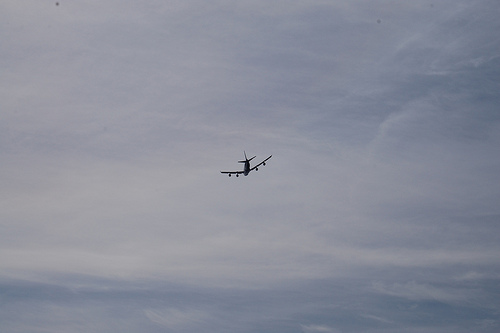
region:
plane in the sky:
[212, 144, 283, 192]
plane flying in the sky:
[212, 141, 277, 190]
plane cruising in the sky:
[213, 140, 280, 196]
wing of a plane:
[214, 162, 250, 180]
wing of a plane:
[248, 149, 275, 179]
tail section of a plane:
[233, 147, 259, 168]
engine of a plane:
[227, 166, 233, 179]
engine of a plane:
[231, 169, 241, 179]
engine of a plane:
[252, 163, 260, 172]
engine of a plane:
[260, 159, 271, 168]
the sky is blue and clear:
[82, 97, 251, 329]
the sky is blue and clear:
[18, 8, 159, 159]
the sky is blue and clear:
[99, 190, 211, 332]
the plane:
[206, 111, 333, 246]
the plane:
[176, 119, 312, 319]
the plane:
[181, 41, 363, 327]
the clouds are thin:
[77, 142, 166, 276]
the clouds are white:
[345, 64, 423, 231]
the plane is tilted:
[222, 141, 281, 193]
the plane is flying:
[206, 139, 276, 191]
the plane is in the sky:
[215, 135, 284, 202]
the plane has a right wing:
[252, 145, 278, 170]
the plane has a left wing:
[217, 163, 243, 181]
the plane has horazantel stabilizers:
[230, 155, 258, 164]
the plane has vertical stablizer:
[237, 147, 251, 160]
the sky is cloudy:
[42, 99, 159, 287]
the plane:
[79, 71, 357, 224]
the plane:
[146, 156, 346, 277]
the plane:
[269, 138, 372, 304]